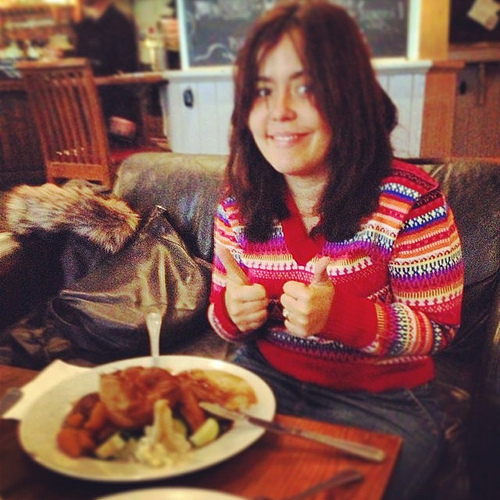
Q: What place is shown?
A: It is a restaurant.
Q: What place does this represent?
A: It represents the restaurant.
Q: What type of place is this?
A: It is a restaurant.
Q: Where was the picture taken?
A: It was taken at the restaurant.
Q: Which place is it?
A: It is a restaurant.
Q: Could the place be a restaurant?
A: Yes, it is a restaurant.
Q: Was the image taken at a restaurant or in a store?
A: It was taken at a restaurant.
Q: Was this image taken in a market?
A: No, the picture was taken in a restaurant.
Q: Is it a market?
A: No, it is a restaurant.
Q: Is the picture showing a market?
A: No, the picture is showing a restaurant.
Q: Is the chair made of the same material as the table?
A: Yes, both the chair and the table are made of wood.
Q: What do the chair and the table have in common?
A: The material, both the chair and the table are wooden.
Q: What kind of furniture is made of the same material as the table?
A: The chair is made of the same material as the table.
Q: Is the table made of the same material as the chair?
A: Yes, both the table and the chair are made of wood.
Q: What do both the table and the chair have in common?
A: The material, both the table and the chair are wooden.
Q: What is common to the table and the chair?
A: The material, both the table and the chair are wooden.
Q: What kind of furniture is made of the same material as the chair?
A: The table is made of the same material as the chair.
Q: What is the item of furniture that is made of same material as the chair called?
A: The piece of furniture is a table.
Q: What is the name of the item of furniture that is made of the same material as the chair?
A: The piece of furniture is a table.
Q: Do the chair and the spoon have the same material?
A: No, the chair is made of wood and the spoon is made of metal.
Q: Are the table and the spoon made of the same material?
A: No, the table is made of wood and the spoon is made of metal.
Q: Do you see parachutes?
A: No, there are no parachutes.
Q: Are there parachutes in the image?
A: No, there are no parachutes.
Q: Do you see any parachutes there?
A: No, there are no parachutes.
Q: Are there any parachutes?
A: No, there are no parachutes.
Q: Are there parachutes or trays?
A: No, there are no parachutes or trays.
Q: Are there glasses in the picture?
A: No, there are no glasses.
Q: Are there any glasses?
A: No, there are no glasses.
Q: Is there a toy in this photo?
A: No, there are no toys.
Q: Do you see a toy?
A: No, there are no toys.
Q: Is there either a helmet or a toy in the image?
A: No, there are no toys or helmets.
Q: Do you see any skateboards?
A: No, there are no skateboards.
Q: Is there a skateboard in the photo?
A: No, there are no skateboards.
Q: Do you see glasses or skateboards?
A: No, there are no skateboards or glasses.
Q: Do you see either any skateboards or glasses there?
A: No, there are no skateboards or glasses.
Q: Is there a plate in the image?
A: Yes, there is a plate.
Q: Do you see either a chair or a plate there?
A: Yes, there is a plate.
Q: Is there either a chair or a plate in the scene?
A: Yes, there is a plate.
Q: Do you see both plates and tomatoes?
A: No, there is a plate but no tomatoes.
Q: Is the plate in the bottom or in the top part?
A: The plate is in the bottom of the image.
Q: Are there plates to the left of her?
A: Yes, there is a plate to the left of the girl.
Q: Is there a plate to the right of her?
A: No, the plate is to the left of the girl.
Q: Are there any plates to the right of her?
A: No, the plate is to the left of the girl.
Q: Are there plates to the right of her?
A: No, the plate is to the left of the girl.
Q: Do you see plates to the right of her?
A: No, the plate is to the left of the girl.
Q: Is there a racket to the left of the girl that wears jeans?
A: No, there is a plate to the left of the girl.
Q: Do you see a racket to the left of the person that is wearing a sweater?
A: No, there is a plate to the left of the girl.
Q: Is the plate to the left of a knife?
A: No, the plate is to the left of the girl.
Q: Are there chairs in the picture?
A: Yes, there is a chair.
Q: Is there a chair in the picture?
A: Yes, there is a chair.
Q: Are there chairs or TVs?
A: Yes, there is a chair.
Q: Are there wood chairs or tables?
A: Yes, there is a wood chair.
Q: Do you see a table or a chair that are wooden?
A: Yes, the chair is wooden.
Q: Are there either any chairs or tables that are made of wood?
A: Yes, the chair is made of wood.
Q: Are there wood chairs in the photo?
A: Yes, there is a wood chair.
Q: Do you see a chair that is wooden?
A: Yes, there is a chair that is wooden.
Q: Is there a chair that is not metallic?
A: Yes, there is a wooden chair.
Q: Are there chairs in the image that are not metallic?
A: Yes, there is a wooden chair.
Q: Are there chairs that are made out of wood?
A: Yes, there is a chair that is made of wood.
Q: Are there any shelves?
A: No, there are no shelves.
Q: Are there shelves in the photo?
A: No, there are no shelves.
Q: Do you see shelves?
A: No, there are no shelves.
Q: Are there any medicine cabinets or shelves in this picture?
A: No, there are no shelves or medicine cabinets.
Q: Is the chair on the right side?
A: No, the chair is on the left of the image.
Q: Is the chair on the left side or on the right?
A: The chair is on the left of the image.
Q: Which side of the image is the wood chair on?
A: The chair is on the left of the image.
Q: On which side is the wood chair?
A: The chair is on the left of the image.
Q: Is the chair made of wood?
A: Yes, the chair is made of wood.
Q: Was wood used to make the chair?
A: Yes, the chair is made of wood.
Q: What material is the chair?
A: The chair is made of wood.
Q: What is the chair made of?
A: The chair is made of wood.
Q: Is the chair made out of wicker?
A: No, the chair is made of wood.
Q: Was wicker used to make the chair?
A: No, the chair is made of wood.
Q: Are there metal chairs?
A: No, there is a chair but it is made of wood.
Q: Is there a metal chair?
A: No, there is a chair but it is made of wood.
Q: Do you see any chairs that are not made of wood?
A: No, there is a chair but it is made of wood.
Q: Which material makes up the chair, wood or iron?
A: The chair is made of wood.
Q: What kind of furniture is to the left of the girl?
A: The piece of furniture is a chair.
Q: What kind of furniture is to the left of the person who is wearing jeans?
A: The piece of furniture is a chair.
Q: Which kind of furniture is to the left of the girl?
A: The piece of furniture is a chair.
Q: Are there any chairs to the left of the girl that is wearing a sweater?
A: Yes, there is a chair to the left of the girl.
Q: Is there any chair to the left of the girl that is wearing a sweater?
A: Yes, there is a chair to the left of the girl.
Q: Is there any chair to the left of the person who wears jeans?
A: Yes, there is a chair to the left of the girl.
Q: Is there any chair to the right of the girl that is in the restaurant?
A: No, the chair is to the left of the girl.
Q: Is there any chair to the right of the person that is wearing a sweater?
A: No, the chair is to the left of the girl.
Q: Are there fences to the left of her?
A: No, there is a chair to the left of the girl.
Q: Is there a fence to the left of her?
A: No, there is a chair to the left of the girl.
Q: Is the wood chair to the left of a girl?
A: Yes, the chair is to the left of a girl.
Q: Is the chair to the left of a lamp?
A: No, the chair is to the left of a girl.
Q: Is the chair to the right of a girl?
A: No, the chair is to the left of a girl.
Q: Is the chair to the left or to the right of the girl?
A: The chair is to the left of the girl.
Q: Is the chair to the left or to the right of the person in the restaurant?
A: The chair is to the left of the girl.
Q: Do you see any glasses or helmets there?
A: No, there are no glasses or helmets.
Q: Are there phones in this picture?
A: No, there are no phones.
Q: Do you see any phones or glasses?
A: No, there are no phones or glasses.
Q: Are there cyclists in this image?
A: No, there are no cyclists.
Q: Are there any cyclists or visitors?
A: No, there are no cyclists or visitors.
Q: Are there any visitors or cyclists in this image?
A: No, there are no cyclists or visitors.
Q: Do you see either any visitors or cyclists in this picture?
A: No, there are no cyclists or visitors.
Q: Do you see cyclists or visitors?
A: No, there are no cyclists or visitors.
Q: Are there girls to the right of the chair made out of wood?
A: Yes, there is a girl to the right of the chair.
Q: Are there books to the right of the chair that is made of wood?
A: No, there is a girl to the right of the chair.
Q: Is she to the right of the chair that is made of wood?
A: Yes, the girl is to the right of the chair.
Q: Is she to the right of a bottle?
A: No, the girl is to the right of the chair.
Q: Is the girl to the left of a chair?
A: No, the girl is to the right of a chair.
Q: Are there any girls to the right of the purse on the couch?
A: Yes, there is a girl to the right of the purse.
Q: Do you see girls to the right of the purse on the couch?
A: Yes, there is a girl to the right of the purse.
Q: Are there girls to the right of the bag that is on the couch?
A: Yes, there is a girl to the right of the purse.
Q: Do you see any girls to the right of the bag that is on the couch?
A: Yes, there is a girl to the right of the purse.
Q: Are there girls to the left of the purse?
A: No, the girl is to the right of the purse.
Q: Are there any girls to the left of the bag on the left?
A: No, the girl is to the right of the purse.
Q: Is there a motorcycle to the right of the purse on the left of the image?
A: No, there is a girl to the right of the purse.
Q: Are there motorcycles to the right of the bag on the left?
A: No, there is a girl to the right of the purse.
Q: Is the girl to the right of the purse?
A: Yes, the girl is to the right of the purse.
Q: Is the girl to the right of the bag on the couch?
A: Yes, the girl is to the right of the purse.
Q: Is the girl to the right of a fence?
A: No, the girl is to the right of the purse.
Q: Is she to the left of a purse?
A: No, the girl is to the right of a purse.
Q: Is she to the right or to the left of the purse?
A: The girl is to the right of the purse.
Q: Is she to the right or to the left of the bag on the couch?
A: The girl is to the right of the purse.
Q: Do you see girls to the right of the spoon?
A: Yes, there is a girl to the right of the spoon.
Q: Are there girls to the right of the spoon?
A: Yes, there is a girl to the right of the spoon.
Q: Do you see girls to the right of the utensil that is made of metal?
A: Yes, there is a girl to the right of the spoon.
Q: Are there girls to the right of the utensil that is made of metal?
A: Yes, there is a girl to the right of the spoon.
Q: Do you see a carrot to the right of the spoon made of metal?
A: No, there is a girl to the right of the spoon.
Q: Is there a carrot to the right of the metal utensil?
A: No, there is a girl to the right of the spoon.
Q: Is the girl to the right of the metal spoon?
A: Yes, the girl is to the right of the spoon.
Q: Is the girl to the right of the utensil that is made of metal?
A: Yes, the girl is to the right of the spoon.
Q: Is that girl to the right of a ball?
A: No, the girl is to the right of the spoon.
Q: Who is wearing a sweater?
A: The girl is wearing a sweater.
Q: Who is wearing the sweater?
A: The girl is wearing a sweater.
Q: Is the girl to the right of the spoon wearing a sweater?
A: Yes, the girl is wearing a sweater.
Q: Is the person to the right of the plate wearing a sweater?
A: Yes, the girl is wearing a sweater.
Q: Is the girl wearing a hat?
A: No, the girl is wearing a sweater.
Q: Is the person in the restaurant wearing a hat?
A: No, the girl is wearing a sweater.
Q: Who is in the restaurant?
A: The girl is in the restaurant.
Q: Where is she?
A: The girl is in the restaurant.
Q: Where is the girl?
A: The girl is in the restaurant.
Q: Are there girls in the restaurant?
A: Yes, there is a girl in the restaurant.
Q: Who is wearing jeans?
A: The girl is wearing jeans.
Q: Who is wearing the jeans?
A: The girl is wearing jeans.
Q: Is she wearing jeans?
A: Yes, the girl is wearing jeans.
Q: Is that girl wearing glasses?
A: No, the girl is wearing jeans.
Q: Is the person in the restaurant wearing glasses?
A: No, the girl is wearing jeans.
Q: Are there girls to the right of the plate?
A: Yes, there is a girl to the right of the plate.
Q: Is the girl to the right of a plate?
A: Yes, the girl is to the right of a plate.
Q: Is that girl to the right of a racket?
A: No, the girl is to the right of a plate.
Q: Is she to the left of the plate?
A: No, the girl is to the right of the plate.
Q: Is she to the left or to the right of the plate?
A: The girl is to the right of the plate.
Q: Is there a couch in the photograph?
A: Yes, there is a couch.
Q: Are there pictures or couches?
A: Yes, there is a couch.